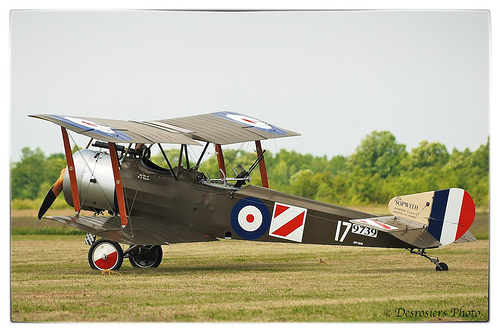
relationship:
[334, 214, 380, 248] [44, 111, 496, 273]
id number on plane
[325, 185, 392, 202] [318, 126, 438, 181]
foliage on nice trees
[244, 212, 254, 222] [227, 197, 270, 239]
dot in circle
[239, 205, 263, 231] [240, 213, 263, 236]
ring around dot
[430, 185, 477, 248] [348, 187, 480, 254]
stripes on tail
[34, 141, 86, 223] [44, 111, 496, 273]
propellar on front of plane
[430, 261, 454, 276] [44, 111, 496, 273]
wheel on plane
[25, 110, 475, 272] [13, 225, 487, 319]
airplane parked in grass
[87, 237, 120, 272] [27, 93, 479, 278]
wheel of an airplane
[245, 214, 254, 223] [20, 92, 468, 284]
dot on an plane